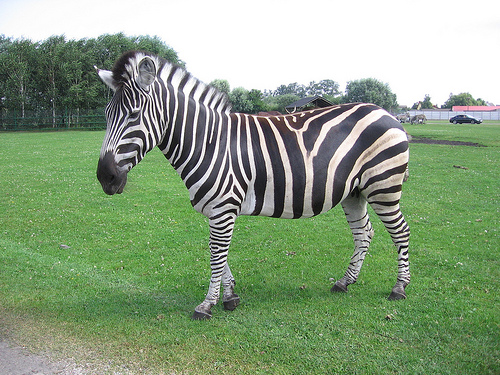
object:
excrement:
[452, 164, 468, 172]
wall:
[407, 110, 500, 120]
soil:
[405, 138, 490, 148]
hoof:
[386, 289, 410, 301]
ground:
[0, 118, 499, 372]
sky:
[0, 0, 497, 106]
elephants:
[410, 116, 426, 125]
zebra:
[94, 53, 411, 317]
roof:
[451, 104, 500, 114]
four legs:
[191, 191, 410, 320]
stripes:
[269, 113, 306, 219]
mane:
[112, 47, 232, 120]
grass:
[0, 116, 500, 375]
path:
[3, 318, 148, 374]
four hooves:
[192, 281, 408, 321]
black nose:
[98, 151, 120, 182]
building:
[450, 105, 499, 126]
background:
[2, 0, 498, 375]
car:
[448, 115, 481, 124]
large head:
[90, 50, 172, 196]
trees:
[0, 33, 33, 120]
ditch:
[406, 135, 494, 147]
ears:
[134, 55, 157, 87]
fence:
[0, 113, 104, 134]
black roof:
[282, 93, 341, 111]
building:
[283, 97, 338, 117]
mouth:
[103, 177, 124, 196]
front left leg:
[192, 204, 238, 321]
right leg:
[222, 264, 236, 313]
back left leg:
[370, 169, 410, 301]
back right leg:
[327, 196, 375, 292]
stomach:
[235, 134, 352, 217]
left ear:
[135, 57, 155, 91]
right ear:
[93, 63, 119, 94]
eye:
[124, 163, 140, 171]